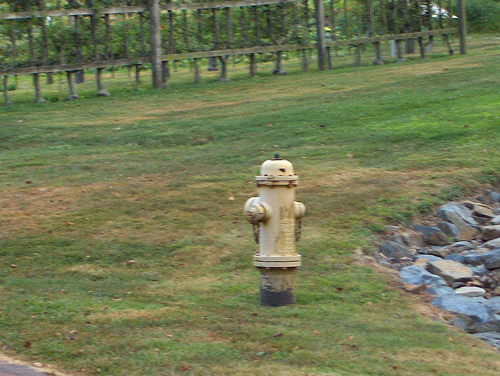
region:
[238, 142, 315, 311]
yellow fire hydrant in the grass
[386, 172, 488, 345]
rocks in a ditch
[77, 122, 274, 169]
green grass on a lawn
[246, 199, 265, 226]
cap on a fire hydrant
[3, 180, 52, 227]
patch of brown grass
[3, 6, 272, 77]
wooden fence on the lawn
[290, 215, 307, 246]
chain on a hydrant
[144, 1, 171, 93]
post to a fence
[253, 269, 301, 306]
bottom of hydrant in the ground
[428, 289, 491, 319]
rock in a ditch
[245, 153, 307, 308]
Yellow fire hydrant in the grass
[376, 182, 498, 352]
Group of rocks piled in the grass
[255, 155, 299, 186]
Rusty dome on top of fire hydrant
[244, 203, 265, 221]
Yellow cap on side of fire hydrant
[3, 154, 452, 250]
Patch of brown grass behind fire hydrant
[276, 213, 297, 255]
Lettering on front of fire hydrant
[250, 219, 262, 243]
Rusty chain on side of fire hydrant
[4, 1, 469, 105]
Wooden fence in the background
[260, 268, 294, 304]
Discolored base on fire hydrant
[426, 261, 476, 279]
Smooth flat jagged rock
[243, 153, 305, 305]
a yellow fire hydrant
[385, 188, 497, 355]
rocks on the side of the grass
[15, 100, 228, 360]
green and yellow grass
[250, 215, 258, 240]
a chain on the fire hydrant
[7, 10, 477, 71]
a fence along the grass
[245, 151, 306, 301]
a fire hydrant in the grass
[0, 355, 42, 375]
portion of asphault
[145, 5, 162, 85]
the trunk of a tree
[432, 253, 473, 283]
a rock in the bed of rocks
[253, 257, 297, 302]
the bottom of the fire hydrant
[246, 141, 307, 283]
tan fire fhydrant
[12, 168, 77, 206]
short green and brown grass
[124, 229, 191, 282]
short green and brown grass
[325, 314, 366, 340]
short green and brown grass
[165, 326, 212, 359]
short green and brown grass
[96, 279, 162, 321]
short green and brown grass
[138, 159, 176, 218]
short green and brown grass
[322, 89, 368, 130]
short green and brown grass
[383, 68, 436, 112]
short green and brown grass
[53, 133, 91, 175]
short green and brown grass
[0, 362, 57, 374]
a patch of asphalt on the ground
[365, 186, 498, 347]
a pit of rocks on the ground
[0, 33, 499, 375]
a large field of grass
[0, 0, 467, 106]
a wooden structure in the field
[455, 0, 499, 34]
a group of trees in the background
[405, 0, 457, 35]
a building in the background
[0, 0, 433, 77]
a large group of green bushes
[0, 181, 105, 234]
a patch of brown grass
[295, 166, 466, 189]
a patch of brown grass